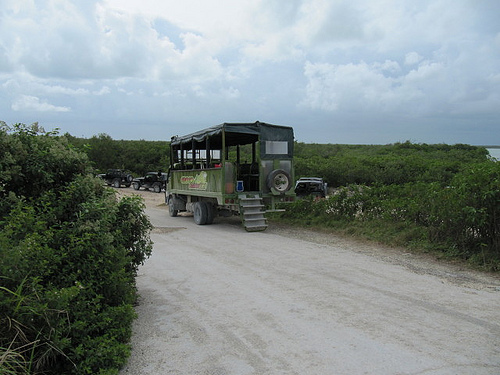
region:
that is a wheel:
[187, 202, 204, 225]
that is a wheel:
[163, 198, 175, 216]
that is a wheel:
[266, 159, 291, 199]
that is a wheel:
[205, 207, 219, 224]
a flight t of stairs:
[243, 191, 266, 233]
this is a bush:
[43, 219, 138, 275]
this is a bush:
[62, 273, 113, 353]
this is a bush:
[17, 132, 75, 223]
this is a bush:
[435, 161, 460, 229]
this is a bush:
[353, 162, 387, 197]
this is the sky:
[283, 28, 466, 101]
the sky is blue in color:
[114, 95, 152, 133]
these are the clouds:
[249, 45, 310, 75]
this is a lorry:
[174, 132, 294, 227]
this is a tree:
[420, 174, 473, 258]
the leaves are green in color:
[61, 156, 98, 250]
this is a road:
[202, 243, 301, 351]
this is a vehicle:
[131, 170, 158, 197]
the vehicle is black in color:
[139, 174, 156, 182]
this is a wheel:
[270, 166, 294, 191]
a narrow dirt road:
[167, 222, 347, 357]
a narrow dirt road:
[216, 266, 449, 368]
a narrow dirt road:
[116, 219, 445, 367]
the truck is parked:
[136, 99, 322, 260]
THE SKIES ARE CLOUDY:
[1, 1, 498, 142]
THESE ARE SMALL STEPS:
[238, 196, 268, 233]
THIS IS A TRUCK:
[164, 118, 297, 234]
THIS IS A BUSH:
[0, 116, 158, 373]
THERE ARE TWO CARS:
[99, 163, 169, 193]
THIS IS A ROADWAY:
[116, 184, 498, 373]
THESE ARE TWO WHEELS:
[166, 194, 207, 224]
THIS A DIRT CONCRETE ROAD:
[114, 188, 499, 374]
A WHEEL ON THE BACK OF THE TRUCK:
[265, 166, 296, 199]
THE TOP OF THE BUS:
[166, 119, 296, 147]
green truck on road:
[145, 72, 297, 231]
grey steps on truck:
[235, 187, 268, 237]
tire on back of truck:
[267, 162, 287, 195]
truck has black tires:
[169, 195, 226, 225]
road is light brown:
[157, 235, 337, 327]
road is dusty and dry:
[126, 205, 431, 366]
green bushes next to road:
[275, 132, 495, 263]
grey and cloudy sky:
[174, 0, 456, 126]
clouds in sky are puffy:
[96, 15, 412, 125]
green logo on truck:
[175, 157, 224, 207]